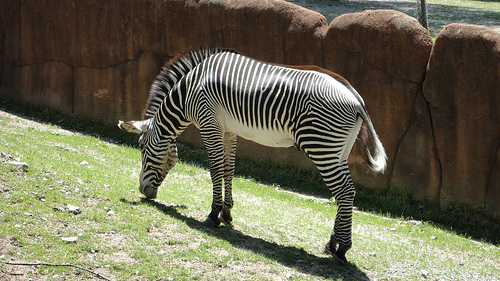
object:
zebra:
[115, 47, 388, 258]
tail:
[358, 104, 389, 174]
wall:
[1, 2, 499, 217]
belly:
[223, 111, 297, 149]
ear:
[115, 118, 153, 134]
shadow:
[1, 93, 500, 248]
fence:
[289, 0, 499, 30]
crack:
[377, 84, 419, 197]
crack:
[417, 89, 445, 214]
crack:
[0, 50, 176, 76]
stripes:
[318, 169, 346, 184]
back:
[307, 156, 341, 162]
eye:
[137, 143, 145, 153]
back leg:
[321, 125, 357, 254]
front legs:
[218, 131, 237, 223]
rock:
[61, 235, 79, 244]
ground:
[0, 100, 498, 280]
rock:
[63, 203, 83, 215]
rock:
[9, 161, 32, 174]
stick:
[4, 259, 112, 280]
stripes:
[336, 207, 353, 214]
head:
[117, 120, 180, 199]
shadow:
[119, 194, 372, 280]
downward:
[136, 132, 179, 199]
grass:
[0, 94, 498, 280]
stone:
[104, 207, 116, 217]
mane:
[139, 47, 224, 120]